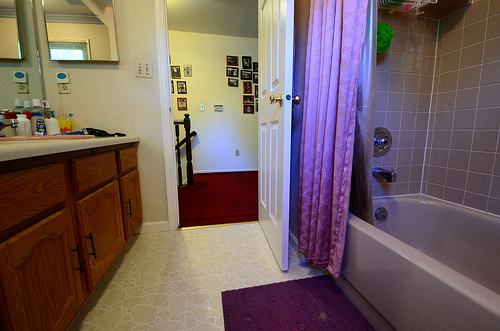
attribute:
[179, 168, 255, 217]
red carpet — outside of bathroom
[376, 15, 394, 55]
green loofah — hanging from shelf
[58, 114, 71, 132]
yellow/red cup — with toothbrush in it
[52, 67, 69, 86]
night light — white and blue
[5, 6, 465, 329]
view — in a washroom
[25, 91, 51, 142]
bottle — mouth wash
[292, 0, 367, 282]
shower curtain — purple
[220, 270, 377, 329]
rug — purple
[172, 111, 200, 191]
railing — black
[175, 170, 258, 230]
carpet — red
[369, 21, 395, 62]
bath sponge — green, hanging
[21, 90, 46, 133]
bottle — mouthwash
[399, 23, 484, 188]
walls — tiled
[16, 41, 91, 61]
window — reflection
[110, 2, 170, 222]
wall — white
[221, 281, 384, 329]
rug — purple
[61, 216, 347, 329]
floor — bathroom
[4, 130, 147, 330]
cabinets — wood, brown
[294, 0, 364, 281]
curtain — shower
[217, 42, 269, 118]
pictures — hung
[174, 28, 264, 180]
wall — white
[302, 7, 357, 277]
curtain — shower, purple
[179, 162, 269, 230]
carpet — red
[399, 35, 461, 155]
tile — tan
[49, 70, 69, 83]
object — blue, white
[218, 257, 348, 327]
bath mat — purple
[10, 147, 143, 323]
vanity — wooden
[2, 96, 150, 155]
counter — white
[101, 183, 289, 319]
tile — white 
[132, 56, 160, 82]
switch — on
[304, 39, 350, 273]
curtain — next to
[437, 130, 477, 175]
tiles — around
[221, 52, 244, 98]
posters — on